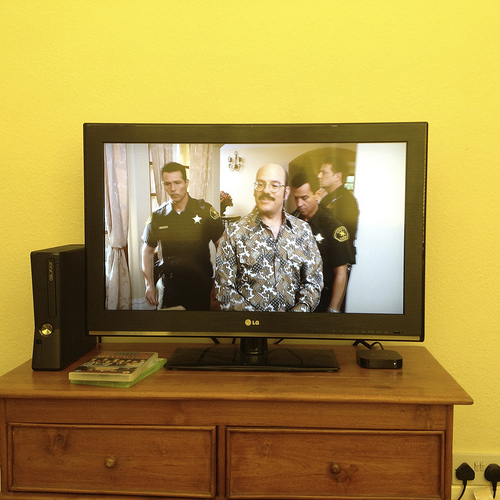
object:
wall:
[2, 0, 500, 498]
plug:
[456, 461, 479, 486]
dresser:
[0, 339, 473, 500]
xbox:
[31, 244, 99, 374]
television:
[80, 120, 430, 378]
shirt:
[212, 205, 329, 311]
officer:
[140, 159, 230, 310]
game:
[66, 346, 169, 391]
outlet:
[450, 452, 500, 488]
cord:
[487, 482, 499, 499]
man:
[212, 158, 326, 313]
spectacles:
[253, 178, 287, 197]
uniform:
[141, 195, 227, 311]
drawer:
[3, 415, 224, 500]